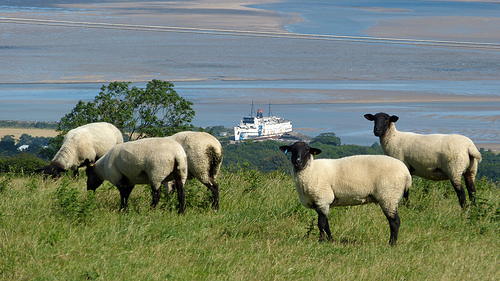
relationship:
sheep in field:
[276, 135, 417, 250] [5, 119, 498, 278]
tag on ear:
[282, 147, 290, 153] [276, 143, 293, 157]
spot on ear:
[87, 160, 95, 166] [81, 160, 95, 172]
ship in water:
[228, 94, 299, 142] [0, 4, 497, 149]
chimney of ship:
[254, 105, 265, 119] [228, 94, 299, 142]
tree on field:
[46, 73, 199, 150] [5, 119, 498, 278]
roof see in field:
[17, 142, 49, 151] [5, 119, 498, 278]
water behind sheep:
[0, 4, 497, 149] [276, 135, 417, 250]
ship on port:
[228, 94, 299, 142] [194, 114, 304, 146]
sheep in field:
[79, 132, 194, 219] [5, 119, 498, 278]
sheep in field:
[358, 102, 487, 216] [5, 119, 498, 278]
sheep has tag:
[276, 135, 417, 250] [282, 147, 290, 153]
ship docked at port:
[228, 94, 299, 142] [194, 114, 304, 146]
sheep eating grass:
[34, 116, 128, 197] [29, 176, 74, 200]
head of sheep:
[275, 138, 327, 174] [276, 135, 417, 250]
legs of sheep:
[308, 209, 414, 255] [276, 135, 417, 250]